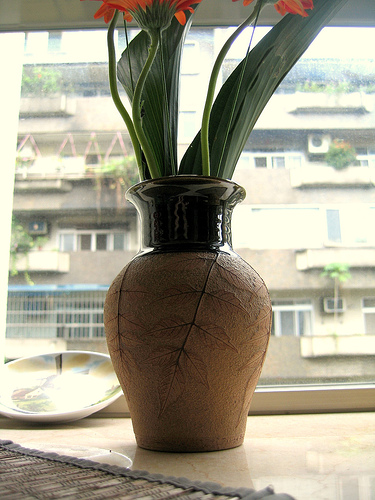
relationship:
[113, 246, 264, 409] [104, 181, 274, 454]
pattern on beige vase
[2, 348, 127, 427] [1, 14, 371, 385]
plate leaning against window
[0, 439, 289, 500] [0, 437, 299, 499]
mat with trim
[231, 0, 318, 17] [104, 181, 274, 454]
flower inside of beige vase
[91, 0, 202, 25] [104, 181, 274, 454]
flower inside of beige vase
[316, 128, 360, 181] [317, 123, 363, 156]
hanging basket with flowers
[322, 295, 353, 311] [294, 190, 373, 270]
air condition on apartment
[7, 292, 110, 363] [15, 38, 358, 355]
fence on building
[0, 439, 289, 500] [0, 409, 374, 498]
mat sitting on tabletop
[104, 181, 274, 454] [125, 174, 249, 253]
beige vase has vase top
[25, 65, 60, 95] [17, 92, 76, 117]
plant on balcony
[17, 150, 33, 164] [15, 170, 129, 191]
plant on balcony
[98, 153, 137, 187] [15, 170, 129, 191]
plant on balcony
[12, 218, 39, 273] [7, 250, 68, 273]
plant on balcony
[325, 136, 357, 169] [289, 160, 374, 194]
plant on balcony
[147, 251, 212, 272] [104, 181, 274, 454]
imprints on beige vase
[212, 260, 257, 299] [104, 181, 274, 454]
imprints on beige vase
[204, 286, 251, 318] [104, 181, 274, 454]
imprints on beige vase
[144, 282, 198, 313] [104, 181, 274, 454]
imprints on beige vase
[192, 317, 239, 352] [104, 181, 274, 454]
imprints on beige vase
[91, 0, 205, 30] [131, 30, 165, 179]
flower has stem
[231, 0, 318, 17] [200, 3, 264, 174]
flower has stem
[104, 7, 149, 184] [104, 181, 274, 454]
stem in beige vase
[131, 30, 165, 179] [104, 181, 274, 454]
stem in beige vase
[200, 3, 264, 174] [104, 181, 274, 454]
stem in beige vase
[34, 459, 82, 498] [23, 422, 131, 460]
mat on table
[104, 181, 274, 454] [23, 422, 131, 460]
beige vase on table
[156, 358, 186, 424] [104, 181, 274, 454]
leaf on beige vase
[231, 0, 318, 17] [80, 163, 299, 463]
flower in beige vase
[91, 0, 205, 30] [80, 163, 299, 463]
flower in beige vase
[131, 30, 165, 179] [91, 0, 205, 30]
stem on flower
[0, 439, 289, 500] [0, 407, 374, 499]
mat on surface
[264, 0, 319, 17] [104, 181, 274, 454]
flower in beige vase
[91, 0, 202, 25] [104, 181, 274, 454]
flower in beige vase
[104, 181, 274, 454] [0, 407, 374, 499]
beige vase sitting on surface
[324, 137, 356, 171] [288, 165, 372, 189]
plant sitting on balcony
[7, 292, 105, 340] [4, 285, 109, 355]
fence on balcony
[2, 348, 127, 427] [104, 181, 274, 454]
plate by beige vase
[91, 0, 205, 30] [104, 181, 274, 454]
flower in beige vase